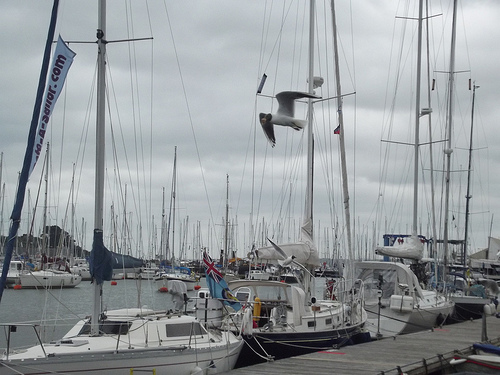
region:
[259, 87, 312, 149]
The bird is in the sky.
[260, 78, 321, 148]
The bird is flying.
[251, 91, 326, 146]
The bird is black and white.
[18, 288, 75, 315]
The water is calm.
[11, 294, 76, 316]
The water is gray.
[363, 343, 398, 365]
The dock is grey.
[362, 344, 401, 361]
The dock is made from wood.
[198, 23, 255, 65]
The clouds are white.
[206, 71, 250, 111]
The sky is gray.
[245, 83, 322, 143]
bird flying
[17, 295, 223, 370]
white boat n harbor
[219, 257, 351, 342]
white boat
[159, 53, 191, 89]
white clouds in blue sky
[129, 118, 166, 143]
white clouds in blue sky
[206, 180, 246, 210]
white clouds in blue sky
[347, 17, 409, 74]
white clouds in blue sky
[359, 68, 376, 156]
white clouds in blue sky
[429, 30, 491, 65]
white clouds in blue sky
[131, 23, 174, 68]
white clouds in blue sky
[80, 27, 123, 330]
tall mast of boat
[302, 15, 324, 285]
tall mast of boat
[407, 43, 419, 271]
tall mast of boat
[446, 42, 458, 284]
tall mast of boat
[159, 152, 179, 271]
tall mast of boat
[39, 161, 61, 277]
tall mast of boat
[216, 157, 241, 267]
tall mast of boat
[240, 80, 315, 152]
bird flying in the air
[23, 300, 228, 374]
boat is docked at pier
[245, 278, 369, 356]
boat is docked at pier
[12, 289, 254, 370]
white boat in water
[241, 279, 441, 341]
white boat in water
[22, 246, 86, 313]
white boat in water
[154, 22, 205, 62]
white clouds in blue sky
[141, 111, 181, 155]
white clouds in blue sky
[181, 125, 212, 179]
white clouds in blue sky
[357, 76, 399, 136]
white clouds in blue sky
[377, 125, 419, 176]
white clouds in blue sky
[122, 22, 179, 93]
white clouds in blue sky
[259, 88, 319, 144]
Seagull flying through the air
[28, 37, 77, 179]
White wind sock with black letters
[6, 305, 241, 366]
White boat in the water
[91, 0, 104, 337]
Tall mast on white boat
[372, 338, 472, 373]
Short fence on boardwalk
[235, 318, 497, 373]
Wooden boardwalk near boats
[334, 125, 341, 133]
Small red flag on boat mast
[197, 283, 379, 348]
Black and white boat near boardwalk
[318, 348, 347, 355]
Red stripe on boardwalk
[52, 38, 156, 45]
Crosspiece on boat mast